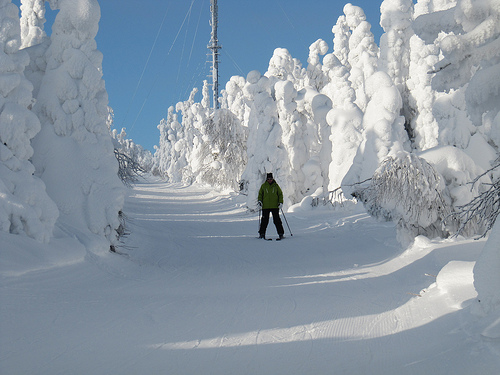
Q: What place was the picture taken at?
A: It was taken at the path.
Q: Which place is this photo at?
A: It is at the path.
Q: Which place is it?
A: It is a path.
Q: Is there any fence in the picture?
A: No, there are no fences.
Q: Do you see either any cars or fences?
A: No, there are no fences or cars.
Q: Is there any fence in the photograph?
A: No, there are no fences.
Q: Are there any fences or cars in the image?
A: No, there are no fences or cars.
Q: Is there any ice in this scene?
A: Yes, there is ice.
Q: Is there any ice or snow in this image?
A: Yes, there is ice.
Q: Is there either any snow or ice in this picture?
A: Yes, there is ice.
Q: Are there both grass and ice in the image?
A: No, there is ice but no grass.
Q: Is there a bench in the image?
A: No, there are no benches.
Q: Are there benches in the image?
A: No, there are no benches.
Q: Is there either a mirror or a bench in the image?
A: No, there are no benches or mirrors.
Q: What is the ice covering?
A: The ice is covering the pole.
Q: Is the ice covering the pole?
A: Yes, the ice is covering the pole.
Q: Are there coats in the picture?
A: Yes, there is a coat.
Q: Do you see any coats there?
A: Yes, there is a coat.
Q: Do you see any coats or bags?
A: Yes, there is a coat.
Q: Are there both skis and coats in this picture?
A: Yes, there are both a coat and skis.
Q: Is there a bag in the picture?
A: No, there are no bags.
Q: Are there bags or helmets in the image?
A: No, there are no bags or helmets.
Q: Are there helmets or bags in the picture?
A: No, there are no bags or helmets.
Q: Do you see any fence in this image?
A: No, there are no fences.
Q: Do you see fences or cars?
A: No, there are no fences or cars.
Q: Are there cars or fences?
A: No, there are no fences or cars.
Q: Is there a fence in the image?
A: No, there are no fences.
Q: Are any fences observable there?
A: No, there are no fences.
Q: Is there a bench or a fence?
A: No, there are no fences or benches.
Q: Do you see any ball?
A: No, there are no balls.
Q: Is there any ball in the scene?
A: No, there are no balls.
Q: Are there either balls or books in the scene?
A: No, there are no balls or books.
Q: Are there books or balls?
A: No, there are no balls or books.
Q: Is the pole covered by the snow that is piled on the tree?
A: Yes, the pole is covered by the snow.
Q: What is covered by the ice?
A: The pole is covered by the ice.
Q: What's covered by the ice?
A: The pole is covered by the ice.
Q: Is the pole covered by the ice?
A: Yes, the pole is covered by the ice.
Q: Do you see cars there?
A: No, there are no cars.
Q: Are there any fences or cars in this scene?
A: No, there are no cars or fences.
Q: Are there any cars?
A: No, there are no cars.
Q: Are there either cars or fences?
A: No, there are no cars or fences.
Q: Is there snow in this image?
A: Yes, there is snow.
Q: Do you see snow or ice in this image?
A: Yes, there is snow.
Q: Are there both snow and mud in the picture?
A: No, there is snow but no mud.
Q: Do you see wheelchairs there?
A: No, there are no wheelchairs.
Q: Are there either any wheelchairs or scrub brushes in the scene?
A: No, there are no wheelchairs or scrub brushes.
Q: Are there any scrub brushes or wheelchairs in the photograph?
A: No, there are no wheelchairs or scrub brushes.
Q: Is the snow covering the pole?
A: Yes, the snow is covering the pole.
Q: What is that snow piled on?
A: The snow is piled on the tree.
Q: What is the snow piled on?
A: The snow is piled on the tree.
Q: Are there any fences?
A: No, there are no fences.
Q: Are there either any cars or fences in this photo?
A: No, there are no fences or cars.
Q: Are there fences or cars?
A: No, there are no cars or fences.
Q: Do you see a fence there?
A: No, there are no fences.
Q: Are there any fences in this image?
A: No, there are no fences.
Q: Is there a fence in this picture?
A: No, there are no fences.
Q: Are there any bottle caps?
A: No, there are no bottle caps.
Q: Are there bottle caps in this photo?
A: No, there are no bottle caps.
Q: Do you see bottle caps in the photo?
A: No, there are no bottle caps.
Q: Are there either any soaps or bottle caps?
A: No, there are no bottle caps or soaps.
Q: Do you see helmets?
A: No, there are no helmets.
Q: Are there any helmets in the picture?
A: No, there are no helmets.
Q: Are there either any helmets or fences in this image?
A: No, there are no helmets or fences.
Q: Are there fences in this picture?
A: No, there are no fences.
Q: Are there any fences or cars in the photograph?
A: No, there are no fences or cars.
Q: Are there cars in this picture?
A: No, there are no cars.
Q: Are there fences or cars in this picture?
A: No, there are no cars or fences.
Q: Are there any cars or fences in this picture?
A: No, there are no cars or fences.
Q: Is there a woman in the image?
A: No, there are no women.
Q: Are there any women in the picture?
A: No, there are no women.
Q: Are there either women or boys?
A: No, there are no women or boys.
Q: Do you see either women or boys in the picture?
A: No, there are no women or boys.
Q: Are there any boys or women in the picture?
A: No, there are no women or boys.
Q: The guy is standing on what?
A: The guy is standing on the ski.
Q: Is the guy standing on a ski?
A: Yes, the guy is standing on a ski.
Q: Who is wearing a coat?
A: The guy is wearing a coat.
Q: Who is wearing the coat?
A: The guy is wearing a coat.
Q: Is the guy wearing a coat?
A: Yes, the guy is wearing a coat.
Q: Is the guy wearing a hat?
A: No, the guy is wearing a coat.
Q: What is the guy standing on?
A: The guy is standing on the ski.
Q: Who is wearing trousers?
A: The guy is wearing trousers.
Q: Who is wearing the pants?
A: The guy is wearing trousers.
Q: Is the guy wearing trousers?
A: Yes, the guy is wearing trousers.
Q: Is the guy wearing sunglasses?
A: No, the guy is wearing trousers.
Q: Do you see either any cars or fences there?
A: No, there are no cars or fences.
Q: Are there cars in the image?
A: No, there are no cars.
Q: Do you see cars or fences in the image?
A: No, there are no cars or fences.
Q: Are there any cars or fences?
A: No, there are no cars or fences.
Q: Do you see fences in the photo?
A: No, there are no fences.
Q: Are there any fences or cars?
A: No, there are no fences or cars.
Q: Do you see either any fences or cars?
A: No, there are no fences or cars.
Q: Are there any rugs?
A: No, there are no rugs.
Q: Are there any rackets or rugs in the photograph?
A: No, there are no rugs or rackets.